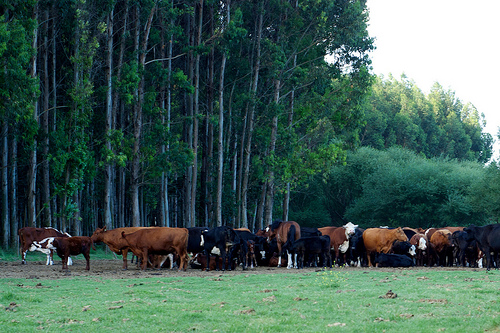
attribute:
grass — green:
[3, 252, 499, 332]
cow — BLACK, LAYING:
[367, 247, 414, 268]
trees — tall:
[3, 0, 377, 217]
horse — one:
[263, 221, 308, 261]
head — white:
[339, 219, 354, 248]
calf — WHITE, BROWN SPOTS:
[23, 233, 59, 266]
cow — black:
[363, 250, 410, 266]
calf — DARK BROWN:
[47, 225, 99, 264]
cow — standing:
[55, 241, 88, 265]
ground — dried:
[16, 260, 101, 272]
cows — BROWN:
[117, 224, 196, 277]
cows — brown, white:
[27, 231, 61, 267]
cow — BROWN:
[317, 220, 357, 268]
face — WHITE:
[343, 221, 356, 237]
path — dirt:
[82, 255, 377, 273]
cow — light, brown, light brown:
[362, 226, 405, 268]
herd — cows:
[17, 217, 499, 267]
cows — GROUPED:
[20, 221, 500, 273]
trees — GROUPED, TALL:
[37, 43, 318, 307]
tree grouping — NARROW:
[1, 2, 377, 237]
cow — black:
[192, 214, 286, 265]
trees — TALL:
[5, 1, 375, 253]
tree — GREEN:
[96, 27, 350, 197]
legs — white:
[279, 246, 300, 267]